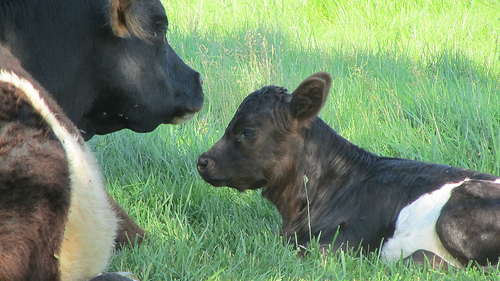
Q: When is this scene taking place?
A: Day time.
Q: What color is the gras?
A: Green.